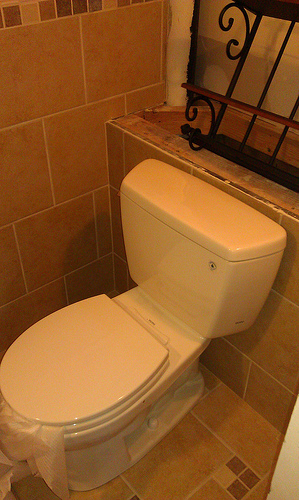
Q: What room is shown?
A: Bathroom.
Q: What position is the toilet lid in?
A: Closed.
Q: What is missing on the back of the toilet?
A: Handle.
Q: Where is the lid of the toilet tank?
A: On the tank.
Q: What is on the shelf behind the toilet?
A: Black iron bars.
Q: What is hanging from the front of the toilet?
A: Paper.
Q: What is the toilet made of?
A: Porcelain.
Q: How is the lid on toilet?
A: Closed.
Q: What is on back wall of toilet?
A: Burglar bar.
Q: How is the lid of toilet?
A: Down.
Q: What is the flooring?
A: Tiles.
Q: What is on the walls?
A: Tiles.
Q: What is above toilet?
A: Window.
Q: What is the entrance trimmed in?
A: White.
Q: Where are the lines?
A: Wall.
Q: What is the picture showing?
A: A toilet.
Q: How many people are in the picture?
A: No one.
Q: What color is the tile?
A: Tan.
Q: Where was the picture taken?
A: In a bathroom.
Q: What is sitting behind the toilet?
A: Window bars.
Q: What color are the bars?
A: Black.